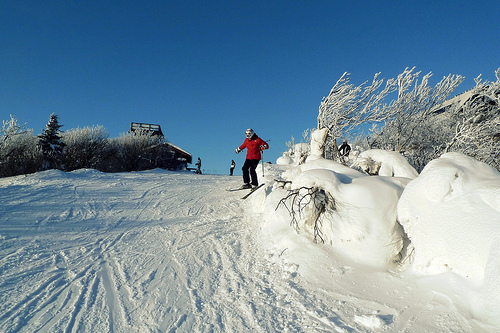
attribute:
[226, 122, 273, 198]
skier — skiing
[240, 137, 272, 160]
jacket — red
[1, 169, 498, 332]
snow — white, present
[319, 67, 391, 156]
trees — frozen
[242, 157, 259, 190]
pants — black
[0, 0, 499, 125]
sky — clear, blue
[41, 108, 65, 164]
tree — green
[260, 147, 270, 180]
pole — black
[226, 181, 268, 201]
skis — black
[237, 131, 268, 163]
coat — red